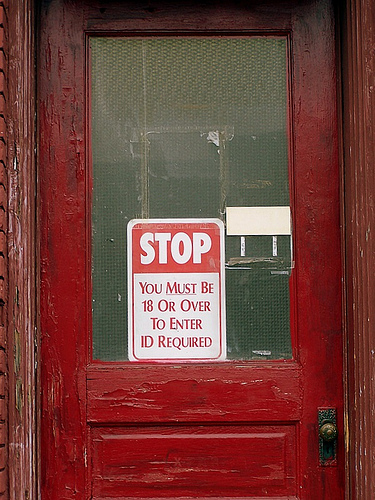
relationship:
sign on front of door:
[124, 214, 230, 363] [38, 0, 347, 499]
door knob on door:
[311, 407, 345, 467] [38, 0, 347, 499]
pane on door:
[84, 35, 300, 362] [38, 0, 347, 499]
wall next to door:
[0, 1, 12, 499] [38, 0, 347, 499]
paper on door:
[220, 198, 293, 239] [38, 0, 347, 499]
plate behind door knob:
[320, 404, 333, 464] [311, 407, 345, 467]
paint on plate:
[324, 457, 337, 469] [320, 404, 333, 464]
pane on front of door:
[84, 35, 300, 362] [38, 0, 347, 499]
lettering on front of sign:
[135, 274, 212, 358] [124, 214, 230, 363]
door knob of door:
[311, 407, 345, 467] [38, 0, 347, 499]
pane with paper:
[84, 35, 300, 362] [220, 198, 293, 239]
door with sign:
[38, 0, 347, 499] [124, 214, 230, 363]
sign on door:
[124, 214, 230, 363] [38, 0, 347, 499]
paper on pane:
[220, 198, 293, 239] [84, 35, 300, 362]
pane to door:
[84, 35, 300, 362] [38, 0, 347, 499]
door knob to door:
[311, 407, 345, 467] [38, 0, 347, 499]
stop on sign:
[135, 229, 212, 265] [124, 214, 230, 363]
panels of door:
[69, 365, 310, 495] [38, 0, 347, 499]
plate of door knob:
[320, 404, 333, 464] [311, 407, 345, 467]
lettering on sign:
[135, 274, 212, 358] [124, 214, 230, 363]